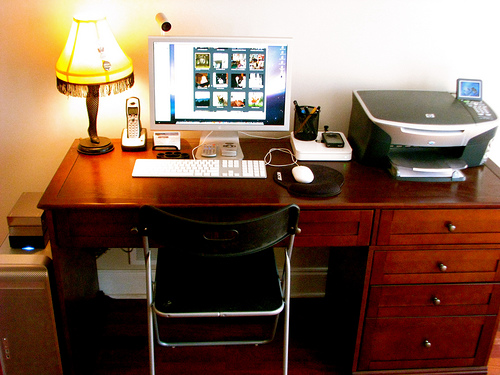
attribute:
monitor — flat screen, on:
[148, 34, 291, 139]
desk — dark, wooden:
[33, 136, 496, 374]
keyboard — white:
[129, 152, 269, 182]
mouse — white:
[291, 164, 320, 187]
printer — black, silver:
[351, 88, 500, 185]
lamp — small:
[56, 11, 133, 162]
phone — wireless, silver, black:
[121, 94, 149, 155]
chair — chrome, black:
[138, 202, 302, 372]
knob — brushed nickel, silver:
[417, 334, 432, 348]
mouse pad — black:
[273, 162, 346, 199]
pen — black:
[291, 100, 315, 132]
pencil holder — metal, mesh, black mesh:
[295, 105, 320, 144]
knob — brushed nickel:
[429, 292, 440, 304]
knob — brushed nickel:
[431, 263, 451, 272]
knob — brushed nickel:
[445, 220, 463, 234]